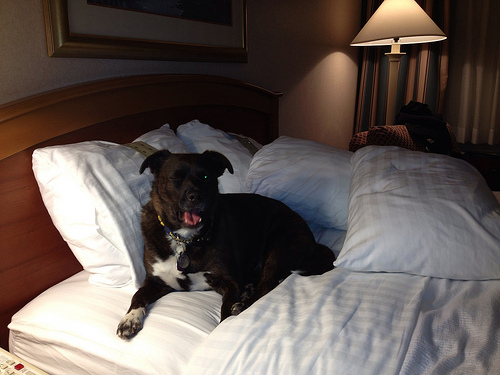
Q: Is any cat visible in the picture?
A: No, there are no cats.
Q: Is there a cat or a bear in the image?
A: No, there are no cats or bears.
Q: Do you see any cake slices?
A: No, there are no cake slices.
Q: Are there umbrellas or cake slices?
A: No, there are no cake slices or umbrellas.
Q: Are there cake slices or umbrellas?
A: No, there are no cake slices or umbrellas.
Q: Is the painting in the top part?
A: Yes, the painting is in the top of the image.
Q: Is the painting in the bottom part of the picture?
A: No, the painting is in the top of the image.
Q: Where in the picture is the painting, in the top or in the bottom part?
A: The painting is in the top of the image.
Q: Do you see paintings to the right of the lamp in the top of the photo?
A: No, the painting is to the left of the lamp.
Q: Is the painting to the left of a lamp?
A: Yes, the painting is to the left of a lamp.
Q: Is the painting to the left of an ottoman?
A: No, the painting is to the left of a lamp.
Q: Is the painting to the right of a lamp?
A: No, the painting is to the left of a lamp.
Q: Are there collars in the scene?
A: Yes, there is a collar.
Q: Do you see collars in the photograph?
A: Yes, there is a collar.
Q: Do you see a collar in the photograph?
A: Yes, there is a collar.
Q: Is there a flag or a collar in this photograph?
A: Yes, there is a collar.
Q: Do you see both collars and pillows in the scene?
A: Yes, there are both a collar and a pillow.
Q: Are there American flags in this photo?
A: No, there are no American flags.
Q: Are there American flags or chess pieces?
A: No, there are no American flags or chess pieces.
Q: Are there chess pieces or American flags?
A: No, there are no American flags or chess pieces.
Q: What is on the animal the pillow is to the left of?
A: The collar is on the dog.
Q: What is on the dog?
A: The collar is on the dog.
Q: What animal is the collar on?
A: The collar is on the dog.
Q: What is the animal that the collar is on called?
A: The animal is a dog.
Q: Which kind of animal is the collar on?
A: The collar is on the dog.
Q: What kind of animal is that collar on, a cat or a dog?
A: The collar is on a dog.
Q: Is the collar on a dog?
A: Yes, the collar is on a dog.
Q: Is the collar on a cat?
A: No, the collar is on a dog.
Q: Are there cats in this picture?
A: No, there are no cats.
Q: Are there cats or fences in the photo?
A: No, there are no cats or fences.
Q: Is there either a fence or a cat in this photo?
A: No, there are no cats or fences.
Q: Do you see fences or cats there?
A: No, there are no cats or fences.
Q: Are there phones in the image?
A: Yes, there is a phone.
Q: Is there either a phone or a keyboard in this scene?
A: Yes, there is a phone.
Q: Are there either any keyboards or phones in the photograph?
A: Yes, there is a phone.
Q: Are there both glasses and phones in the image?
A: No, there is a phone but no glasses.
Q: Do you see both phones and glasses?
A: No, there is a phone but no glasses.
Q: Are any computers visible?
A: No, there are no computers.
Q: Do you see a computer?
A: No, there are no computers.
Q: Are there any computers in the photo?
A: No, there are no computers.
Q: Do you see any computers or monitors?
A: No, there are no computers or monitors.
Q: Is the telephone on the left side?
A: Yes, the telephone is on the left of the image.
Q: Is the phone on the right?
A: No, the phone is on the left of the image.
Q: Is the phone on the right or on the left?
A: The phone is on the left of the image.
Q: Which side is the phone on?
A: The phone is on the left of the image.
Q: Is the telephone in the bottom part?
A: Yes, the telephone is in the bottom of the image.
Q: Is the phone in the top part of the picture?
A: No, the phone is in the bottom of the image.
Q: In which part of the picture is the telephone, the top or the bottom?
A: The telephone is in the bottom of the image.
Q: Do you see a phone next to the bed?
A: Yes, there is a phone next to the bed.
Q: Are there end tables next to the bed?
A: No, there is a phone next to the bed.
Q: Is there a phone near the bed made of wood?
A: Yes, there is a phone near the bed.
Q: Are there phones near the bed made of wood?
A: Yes, there is a phone near the bed.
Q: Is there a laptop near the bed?
A: No, there is a phone near the bed.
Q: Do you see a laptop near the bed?
A: No, there is a phone near the bed.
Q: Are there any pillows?
A: Yes, there is a pillow.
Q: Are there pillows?
A: Yes, there is a pillow.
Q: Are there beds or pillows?
A: Yes, there is a pillow.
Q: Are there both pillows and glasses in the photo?
A: No, there is a pillow but no glasses.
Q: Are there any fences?
A: No, there are no fences.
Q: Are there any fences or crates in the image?
A: No, there are no fences or crates.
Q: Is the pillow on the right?
A: No, the pillow is on the left of the image.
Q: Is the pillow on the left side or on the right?
A: The pillow is on the left of the image.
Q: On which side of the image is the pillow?
A: The pillow is on the left of the image.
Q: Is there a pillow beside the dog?
A: Yes, there is a pillow beside the dog.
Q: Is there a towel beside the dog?
A: No, there is a pillow beside the dog.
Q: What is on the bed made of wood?
A: The pillow is on the bed.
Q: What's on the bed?
A: The pillow is on the bed.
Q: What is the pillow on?
A: The pillow is on the bed.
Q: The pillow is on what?
A: The pillow is on the bed.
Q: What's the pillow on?
A: The pillow is on the bed.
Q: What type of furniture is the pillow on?
A: The pillow is on the bed.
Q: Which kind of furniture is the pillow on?
A: The pillow is on the bed.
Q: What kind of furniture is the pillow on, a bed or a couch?
A: The pillow is on a bed.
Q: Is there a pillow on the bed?
A: Yes, there is a pillow on the bed.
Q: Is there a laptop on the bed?
A: No, there is a pillow on the bed.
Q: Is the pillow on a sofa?
A: No, the pillow is on the bed.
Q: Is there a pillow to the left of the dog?
A: Yes, there is a pillow to the left of the dog.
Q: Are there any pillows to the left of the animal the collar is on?
A: Yes, there is a pillow to the left of the dog.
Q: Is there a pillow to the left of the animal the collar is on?
A: Yes, there is a pillow to the left of the dog.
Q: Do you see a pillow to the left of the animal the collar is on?
A: Yes, there is a pillow to the left of the dog.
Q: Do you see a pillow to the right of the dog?
A: No, the pillow is to the left of the dog.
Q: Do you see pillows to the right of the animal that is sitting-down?
A: No, the pillow is to the left of the dog.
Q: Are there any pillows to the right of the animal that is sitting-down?
A: No, the pillow is to the left of the dog.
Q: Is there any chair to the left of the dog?
A: No, there is a pillow to the left of the dog.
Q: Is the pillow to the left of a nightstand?
A: No, the pillow is to the left of a dog.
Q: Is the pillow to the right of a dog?
A: No, the pillow is to the left of a dog.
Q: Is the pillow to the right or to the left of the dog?
A: The pillow is to the left of the dog.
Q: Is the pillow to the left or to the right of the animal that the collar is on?
A: The pillow is to the left of the dog.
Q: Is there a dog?
A: Yes, there is a dog.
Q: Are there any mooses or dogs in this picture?
A: Yes, there is a dog.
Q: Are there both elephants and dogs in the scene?
A: No, there is a dog but no elephants.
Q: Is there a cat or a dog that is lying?
A: Yes, the dog is lying.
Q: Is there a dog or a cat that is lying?
A: Yes, the dog is lying.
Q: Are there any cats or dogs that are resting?
A: Yes, the dog is resting.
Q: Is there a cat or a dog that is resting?
A: Yes, the dog is resting.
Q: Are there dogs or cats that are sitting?
A: Yes, the dog is sitting.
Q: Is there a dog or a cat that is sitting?
A: Yes, the dog is sitting.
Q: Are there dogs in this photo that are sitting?
A: Yes, there is a dog that is sitting.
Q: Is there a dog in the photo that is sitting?
A: Yes, there is a dog that is sitting.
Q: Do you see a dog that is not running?
A: Yes, there is a dog that is sitting .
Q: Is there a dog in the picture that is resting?
A: Yes, there is a dog that is resting.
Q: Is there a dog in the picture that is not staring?
A: Yes, there is a dog that is resting.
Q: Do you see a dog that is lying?
A: Yes, there is a dog that is lying.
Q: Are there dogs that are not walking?
A: Yes, there is a dog that is lying.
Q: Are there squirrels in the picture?
A: No, there are no squirrels.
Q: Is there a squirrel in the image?
A: No, there are no squirrels.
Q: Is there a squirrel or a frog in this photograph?
A: No, there are no squirrels or frogs.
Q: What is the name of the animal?
A: The animal is a dog.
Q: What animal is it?
A: The animal is a dog.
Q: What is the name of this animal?
A: This is a dog.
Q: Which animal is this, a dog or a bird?
A: This is a dog.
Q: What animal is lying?
A: The animal is a dog.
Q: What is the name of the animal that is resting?
A: The animal is a dog.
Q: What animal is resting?
A: The animal is a dog.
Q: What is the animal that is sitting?
A: The animal is a dog.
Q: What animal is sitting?
A: The animal is a dog.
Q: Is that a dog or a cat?
A: That is a dog.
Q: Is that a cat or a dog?
A: That is a dog.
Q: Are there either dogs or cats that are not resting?
A: No, there is a dog but it is resting.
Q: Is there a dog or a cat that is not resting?
A: No, there is a dog but it is resting.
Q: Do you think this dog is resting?
A: Yes, the dog is resting.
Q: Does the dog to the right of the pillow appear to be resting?
A: Yes, the dog is resting.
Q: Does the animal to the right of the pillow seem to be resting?
A: Yes, the dog is resting.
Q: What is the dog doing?
A: The dog is resting.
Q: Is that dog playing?
A: No, the dog is resting.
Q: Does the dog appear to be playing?
A: No, the dog is resting.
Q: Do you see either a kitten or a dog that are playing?
A: No, there is a dog but it is resting.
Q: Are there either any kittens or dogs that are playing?
A: No, there is a dog but it is resting.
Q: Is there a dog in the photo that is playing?
A: No, there is a dog but it is resting.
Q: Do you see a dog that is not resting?
A: No, there is a dog but it is resting.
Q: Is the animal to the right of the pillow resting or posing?
A: The dog is resting.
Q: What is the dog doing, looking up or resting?
A: The dog is resting.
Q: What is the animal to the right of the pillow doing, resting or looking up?
A: The dog is resting.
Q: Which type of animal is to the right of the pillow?
A: The animal is a dog.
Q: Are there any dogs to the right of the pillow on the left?
A: Yes, there is a dog to the right of the pillow.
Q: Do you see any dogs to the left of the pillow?
A: No, the dog is to the right of the pillow.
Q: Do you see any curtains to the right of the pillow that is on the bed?
A: No, there is a dog to the right of the pillow.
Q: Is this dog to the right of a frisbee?
A: No, the dog is to the right of the pillow.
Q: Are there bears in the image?
A: No, there are no bears.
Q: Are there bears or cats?
A: No, there are no bears or cats.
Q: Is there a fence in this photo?
A: No, there are no fences.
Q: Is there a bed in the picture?
A: Yes, there is a bed.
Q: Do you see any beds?
A: Yes, there is a bed.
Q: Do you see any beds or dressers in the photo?
A: Yes, there is a bed.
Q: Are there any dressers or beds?
A: Yes, there is a bed.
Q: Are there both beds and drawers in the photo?
A: No, there is a bed but no drawers.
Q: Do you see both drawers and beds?
A: No, there is a bed but no drawers.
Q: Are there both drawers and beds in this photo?
A: No, there is a bed but no drawers.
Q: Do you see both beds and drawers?
A: No, there is a bed but no drawers.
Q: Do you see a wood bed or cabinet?
A: Yes, there is a wood bed.